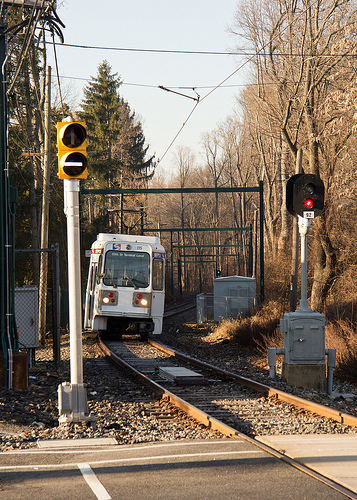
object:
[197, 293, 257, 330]
fence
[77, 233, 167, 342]
train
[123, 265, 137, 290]
windshield wiper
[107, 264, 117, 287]
windshield wiper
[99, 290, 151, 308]
headlights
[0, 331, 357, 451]
pepples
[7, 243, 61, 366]
fence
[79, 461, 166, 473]
shadow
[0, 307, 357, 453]
gravel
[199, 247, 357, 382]
grass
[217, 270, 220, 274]
green light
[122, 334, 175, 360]
sun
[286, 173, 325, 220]
signal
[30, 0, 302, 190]
sky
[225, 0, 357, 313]
trees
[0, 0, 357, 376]
wooded area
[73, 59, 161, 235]
tree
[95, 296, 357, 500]
railroad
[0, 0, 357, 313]
woods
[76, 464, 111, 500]
lines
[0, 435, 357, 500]
road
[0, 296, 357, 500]
ground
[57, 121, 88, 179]
signal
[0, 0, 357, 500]
area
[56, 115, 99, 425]
traffic light